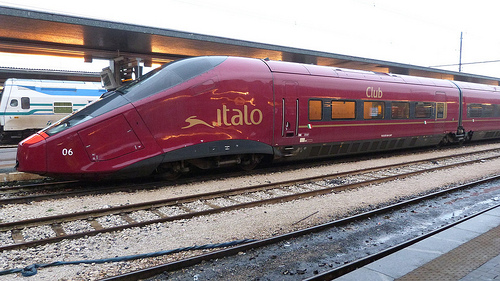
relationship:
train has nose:
[37, 80, 497, 144] [48, 71, 244, 159]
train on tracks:
[37, 80, 497, 144] [208, 177, 227, 204]